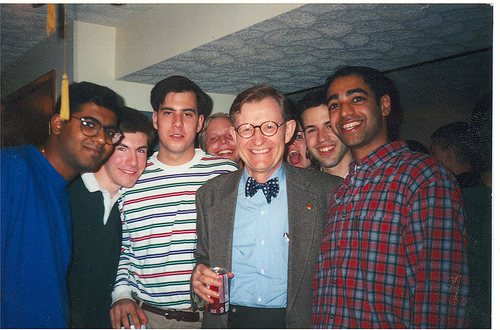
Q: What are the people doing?
A: Smiling.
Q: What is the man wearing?
A: Shirt.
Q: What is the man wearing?
A: Plain shirt.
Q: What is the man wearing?
A: Suit.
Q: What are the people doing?
A: Taking picture.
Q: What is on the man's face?
A: Glasses.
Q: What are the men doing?
A: Posing.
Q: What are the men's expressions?
A: Smiles.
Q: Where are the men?
A: Inside a room.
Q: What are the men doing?
A: Smiling.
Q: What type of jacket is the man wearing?
A: Suit jacket.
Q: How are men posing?
A: In a group.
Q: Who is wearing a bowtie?
A: Man in gray suit.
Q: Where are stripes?
A: On white shirt.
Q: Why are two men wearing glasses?
A: To see better.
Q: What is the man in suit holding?
A: Soda can.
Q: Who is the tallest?
A: Man in white shirt.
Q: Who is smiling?
A: All the men.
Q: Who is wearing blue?
A: Man on the left.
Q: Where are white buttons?
A: On blue shirt.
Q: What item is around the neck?
A: A bowtie.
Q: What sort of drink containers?
A: Cans.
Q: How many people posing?
A: Eight.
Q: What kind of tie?
A: Bow tie.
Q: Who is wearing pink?
A: Bow tie man.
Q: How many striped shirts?
A: One.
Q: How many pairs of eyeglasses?
A: Two.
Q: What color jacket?
A: Grey.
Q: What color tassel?
A: Yellow.